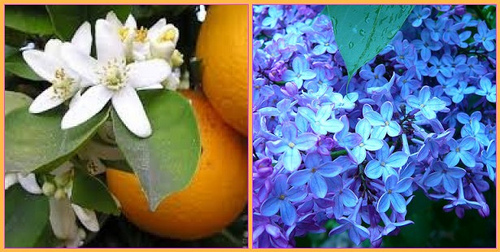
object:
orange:
[100, 87, 248, 244]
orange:
[194, 5, 247, 134]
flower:
[49, 16, 175, 139]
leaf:
[105, 88, 209, 216]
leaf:
[5, 103, 113, 181]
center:
[93, 58, 138, 91]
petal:
[94, 8, 129, 69]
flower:
[361, 100, 403, 146]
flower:
[395, 65, 422, 100]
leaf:
[325, 0, 417, 87]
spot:
[371, 54, 399, 80]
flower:
[442, 78, 478, 104]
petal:
[109, 85, 155, 139]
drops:
[347, 41, 355, 50]